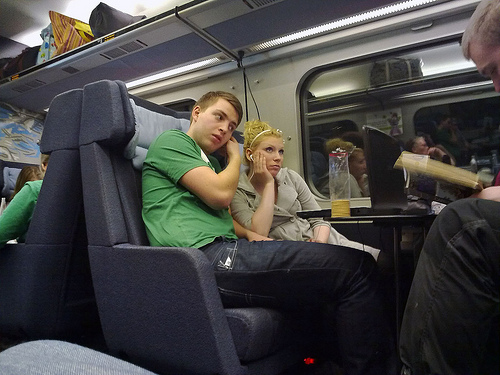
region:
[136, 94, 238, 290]
boy wearing green shirt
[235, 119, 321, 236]
girl with blonde hair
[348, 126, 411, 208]
laptop on bus table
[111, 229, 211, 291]
arm rest on chair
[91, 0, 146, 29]
duffel bag on shelf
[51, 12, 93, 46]
duffel bag on shelf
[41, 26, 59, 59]
duffel bag on shelf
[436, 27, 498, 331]
man sitting opposite from kids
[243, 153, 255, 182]
ear buds in girls ear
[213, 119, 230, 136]
nose on boy's face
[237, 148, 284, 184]
right hand of woman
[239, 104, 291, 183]
head of the woman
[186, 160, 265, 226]
right elbow of guy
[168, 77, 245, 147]
head of the guy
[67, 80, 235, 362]
navy blue seat of train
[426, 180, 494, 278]
left knee of someone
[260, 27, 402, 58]
overhead light of train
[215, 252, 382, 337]
blue jeans of guy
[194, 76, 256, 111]
brunette hair of guy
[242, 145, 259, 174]
right headphone on girl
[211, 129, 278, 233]
People listening to music.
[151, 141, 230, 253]
The shirt is green.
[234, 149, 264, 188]
The earbuds are white.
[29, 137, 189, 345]
The chair is blue.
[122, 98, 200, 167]
Cushion for the head.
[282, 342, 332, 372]
A red light shining.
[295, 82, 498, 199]
Reflection in the window.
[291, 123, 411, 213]
The laptop is black.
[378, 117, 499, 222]
The man is reading.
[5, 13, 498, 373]
Was taken on a bus.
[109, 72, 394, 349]
two people sharing headphones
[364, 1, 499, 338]
man reading a book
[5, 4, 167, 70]
baggage in overhead compartment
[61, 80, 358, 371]
blue chair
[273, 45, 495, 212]
train window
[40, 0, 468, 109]
fluorescent lights overhead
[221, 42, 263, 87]
electrical outlet in the ceiling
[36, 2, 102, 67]
red and yellow bag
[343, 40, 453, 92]
reflection of bag in the window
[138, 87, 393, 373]
man in a green shirt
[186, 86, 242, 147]
the head of a man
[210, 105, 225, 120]
the eye of a man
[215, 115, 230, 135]
the nose of a man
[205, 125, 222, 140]
the mouth of a man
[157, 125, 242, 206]
the arm of a man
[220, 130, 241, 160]
the hand of a man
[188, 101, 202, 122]
the eye of a man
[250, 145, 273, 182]
the hand of a woman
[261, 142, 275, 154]
the eye of a woman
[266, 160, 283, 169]
the mouth of a woman